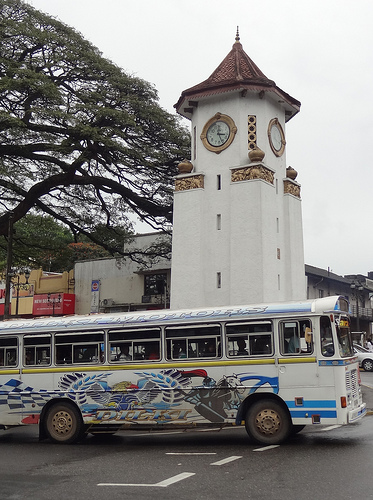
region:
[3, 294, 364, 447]
A white bus.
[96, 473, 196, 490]
A white line on the road.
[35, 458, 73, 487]
Part of the road.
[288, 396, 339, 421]
Blue lines on the bus.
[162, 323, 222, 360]
A passenger window.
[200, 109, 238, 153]
A clock on a building.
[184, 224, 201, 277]
Part of the white building.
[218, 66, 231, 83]
Part of the roof.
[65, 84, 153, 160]
Part of the tree.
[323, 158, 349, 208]
Part of the sky.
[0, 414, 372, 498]
an asphalt road with white lines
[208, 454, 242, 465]
a white line on the road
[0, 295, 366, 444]
a colorful commuter bus on the road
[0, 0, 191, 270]
a large green tree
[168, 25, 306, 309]
a white clock tower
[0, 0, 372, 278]
a large area of white sky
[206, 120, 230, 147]
a clock on the tower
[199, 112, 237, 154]
an ornate frame around a clock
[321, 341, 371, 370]
a car in the distance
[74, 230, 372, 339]
a white building in the background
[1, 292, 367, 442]
PASSENGER BUS ON STREET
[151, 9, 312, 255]
TOWER ON CORNER OF BUILDING BEHIND BUS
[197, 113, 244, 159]
CLOCK ON LEFT SIDE OF TOWER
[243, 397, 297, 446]
LARGE TIRE ON BUS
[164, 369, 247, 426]
KNIGHT ON HORSE DEPICTED ON SIDE OF BUS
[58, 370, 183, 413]
IMAGE OF LARGE BIRD ON SIDE OF BUS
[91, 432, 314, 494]
WHITE LINES ON STREET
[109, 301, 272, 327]
BUS SAYS MOTORS ON TOP AREA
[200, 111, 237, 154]
FRAME OF CLOCK IS GOLD IN COLOR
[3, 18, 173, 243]
LARGE TREE ABOVE STREET AND BUILDINGS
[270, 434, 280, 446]
part of a wheel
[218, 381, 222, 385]
side of a bus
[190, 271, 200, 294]
part of a wall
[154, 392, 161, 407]
edge of a bus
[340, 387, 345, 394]
part of a light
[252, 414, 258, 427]
edge of a wheel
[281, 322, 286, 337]
part of a window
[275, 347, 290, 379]
side of a bus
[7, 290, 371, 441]
older white bus painted with a colorful ornate design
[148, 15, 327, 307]
tall white clock tower behind the bus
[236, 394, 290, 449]
black front wheel of the white bus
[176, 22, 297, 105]
pointed tiled roof of the clock tower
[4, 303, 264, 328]
name of the bus company in white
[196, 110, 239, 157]
clock enclosed with a gold ring on the tower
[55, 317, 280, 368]
several windows on the bus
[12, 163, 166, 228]
large bare branch from a tree nearby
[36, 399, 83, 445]
rear black tire of the white bus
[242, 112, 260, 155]
ornate gold design on the clock tower